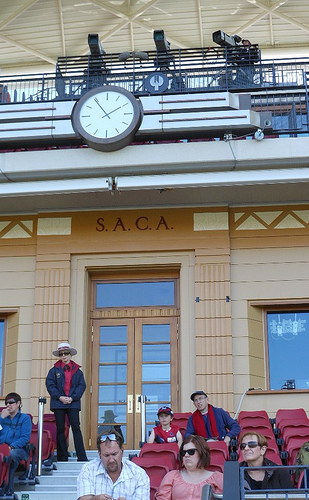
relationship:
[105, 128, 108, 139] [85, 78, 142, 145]
line on clock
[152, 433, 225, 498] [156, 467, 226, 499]
woman with a shirt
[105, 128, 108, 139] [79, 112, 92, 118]
line representing number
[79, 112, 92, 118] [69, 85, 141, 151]
number on clock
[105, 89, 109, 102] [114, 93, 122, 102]
black line representing number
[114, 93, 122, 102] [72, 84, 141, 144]
number on clock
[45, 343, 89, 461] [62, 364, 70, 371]
woman wearing a tie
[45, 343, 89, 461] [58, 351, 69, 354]
woman wearing sunglasses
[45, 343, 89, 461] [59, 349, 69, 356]
woman wearing sunglasses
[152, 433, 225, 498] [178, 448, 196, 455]
woman wearing sunglasses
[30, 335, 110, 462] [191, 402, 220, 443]
man wearing red scarf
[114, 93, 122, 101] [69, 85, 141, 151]
number on clock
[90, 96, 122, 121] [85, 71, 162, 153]
line on clock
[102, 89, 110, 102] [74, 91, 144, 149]
black line on clock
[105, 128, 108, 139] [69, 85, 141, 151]
line on clock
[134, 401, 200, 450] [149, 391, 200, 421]
child wearing hat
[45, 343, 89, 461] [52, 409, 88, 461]
woman wearing black pants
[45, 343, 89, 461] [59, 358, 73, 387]
woman wearing shirt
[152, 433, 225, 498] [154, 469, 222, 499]
woman wearing shirt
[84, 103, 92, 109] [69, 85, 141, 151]
line representing number on clock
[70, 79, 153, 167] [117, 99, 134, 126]
clock with a white face and brown numbers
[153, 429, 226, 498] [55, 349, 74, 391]
woman wearing a white hat and sunglasses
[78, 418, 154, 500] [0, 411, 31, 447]
man wearing sunglasses and a blue jacket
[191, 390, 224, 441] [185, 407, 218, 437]
man wearing a blue jacket and red scarf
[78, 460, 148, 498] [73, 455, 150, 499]
man wearing a white shirt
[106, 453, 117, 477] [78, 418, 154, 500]
eye of a man